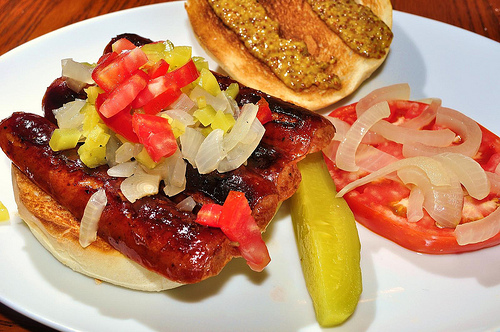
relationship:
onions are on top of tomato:
[354, 85, 490, 215] [307, 88, 497, 250]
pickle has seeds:
[292, 147, 367, 331] [313, 207, 342, 265]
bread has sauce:
[185, 4, 401, 114] [210, 0, 394, 90]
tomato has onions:
[307, 88, 497, 250] [354, 85, 490, 215]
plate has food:
[7, 8, 498, 329] [11, 17, 500, 324]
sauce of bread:
[210, 0, 394, 90] [185, 4, 401, 114]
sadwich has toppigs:
[11, 17, 500, 324] [88, 36, 498, 314]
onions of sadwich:
[175, 98, 263, 175] [11, 17, 500, 324]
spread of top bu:
[210, 0, 394, 90] [185, 4, 401, 114]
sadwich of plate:
[12, 18, 325, 304] [7, 8, 498, 329]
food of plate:
[11, 17, 500, 324] [7, 8, 498, 329]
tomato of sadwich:
[93, 38, 191, 156] [12, 18, 325, 304]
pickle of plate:
[292, 147, 367, 331] [7, 8, 498, 329]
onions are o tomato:
[354, 85, 490, 215] [307, 88, 497, 250]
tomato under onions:
[307, 88, 497, 250] [354, 85, 490, 215]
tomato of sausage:
[93, 38, 191, 156] [10, 29, 334, 307]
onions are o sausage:
[175, 98, 263, 175] [10, 29, 334, 307]